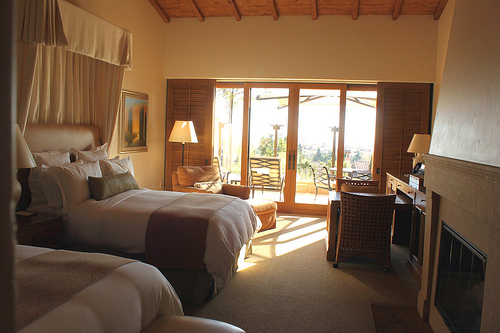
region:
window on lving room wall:
[167, 78, 433, 232]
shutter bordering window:
[161, 78, 213, 195]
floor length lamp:
[165, 115, 200, 165]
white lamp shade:
[161, 118, 204, 150]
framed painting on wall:
[116, 80, 161, 160]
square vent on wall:
[430, 202, 499, 332]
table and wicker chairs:
[312, 167, 409, 283]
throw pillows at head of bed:
[27, 143, 140, 208]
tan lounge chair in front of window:
[168, 156, 290, 237]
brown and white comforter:
[60, 186, 265, 280]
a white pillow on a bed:
[50, 158, 105, 215]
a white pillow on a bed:
[103, 155, 143, 189]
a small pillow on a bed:
[87, 168, 139, 202]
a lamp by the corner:
[168, 118, 196, 208]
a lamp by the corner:
[405, 130, 435, 182]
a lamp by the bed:
[10, 118, 40, 248]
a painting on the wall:
[119, 89, 149, 154]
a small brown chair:
[246, 153, 291, 200]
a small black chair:
[305, 160, 339, 202]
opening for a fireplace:
[430, 224, 487, 330]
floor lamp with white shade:
[166, 119, 198, 165]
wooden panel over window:
[374, 81, 431, 197]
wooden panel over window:
[164, 77, 216, 192]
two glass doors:
[242, 77, 347, 217]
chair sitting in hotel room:
[170, 163, 276, 233]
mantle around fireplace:
[415, 151, 497, 332]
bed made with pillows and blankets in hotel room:
[21, 125, 264, 309]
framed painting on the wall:
[119, 89, 148, 152]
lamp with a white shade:
[406, 132, 431, 169]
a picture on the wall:
[120, 87, 150, 153]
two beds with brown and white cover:
[11, 149, 261, 331]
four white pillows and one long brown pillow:
[36, 144, 138, 201]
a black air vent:
[430, 218, 490, 330]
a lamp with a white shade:
[12, 120, 33, 206]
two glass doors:
[241, 84, 344, 219]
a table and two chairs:
[323, 172, 395, 274]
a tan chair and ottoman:
[171, 163, 278, 231]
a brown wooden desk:
[381, 170, 428, 272]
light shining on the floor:
[235, 212, 327, 269]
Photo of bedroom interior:
[27, 7, 497, 329]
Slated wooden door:
[163, 75, 215, 182]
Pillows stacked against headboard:
[20, 116, 144, 209]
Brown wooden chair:
[334, 186, 401, 275]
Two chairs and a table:
[318, 172, 409, 269]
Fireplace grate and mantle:
[414, 150, 499, 327]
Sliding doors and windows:
[213, 78, 380, 213]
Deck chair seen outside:
[248, 153, 284, 200]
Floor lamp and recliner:
[161, 120, 253, 202]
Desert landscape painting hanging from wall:
[118, 84, 153, 153]